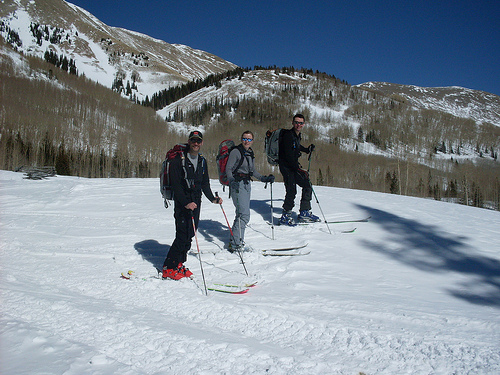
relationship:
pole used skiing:
[193, 190, 252, 301] [138, 180, 466, 365]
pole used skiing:
[244, 152, 303, 262] [35, 81, 475, 344]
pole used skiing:
[186, 200, 211, 299] [7, 100, 442, 358]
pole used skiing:
[178, 152, 316, 302] [17, 35, 477, 365]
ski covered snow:
[253, 234, 325, 266] [308, 266, 413, 306]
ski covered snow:
[244, 240, 317, 257] [300, 312, 411, 361]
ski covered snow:
[244, 240, 317, 257] [267, 320, 420, 365]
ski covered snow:
[119, 266, 259, 296] [249, 238, 305, 262]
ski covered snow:
[244, 236, 322, 264] [234, 319, 390, 358]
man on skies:
[275, 110, 321, 227] [195, 150, 361, 300]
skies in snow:
[195, 173, 378, 300] [292, 312, 421, 369]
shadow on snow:
[347, 202, 450, 264] [283, 326, 401, 364]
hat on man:
[183, 129, 205, 147] [144, 123, 236, 290]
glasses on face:
[237, 133, 253, 143] [242, 132, 253, 149]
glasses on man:
[237, 133, 253, 143] [227, 120, 261, 255]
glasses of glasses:
[237, 135, 253, 143] [240, 137, 256, 147]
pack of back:
[264, 125, 284, 164] [274, 130, 288, 166]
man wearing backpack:
[270, 106, 324, 235] [259, 128, 288, 172]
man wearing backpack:
[225, 127, 274, 255] [208, 134, 243, 191]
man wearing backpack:
[158, 129, 223, 281] [156, 142, 184, 206]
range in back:
[0, 0, 495, 219] [3, 3, 498, 213]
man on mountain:
[199, 106, 275, 278] [11, 128, 465, 373]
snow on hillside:
[0, 169, 499, 375] [29, 175, 431, 373]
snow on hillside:
[0, 169, 499, 375] [22, 158, 495, 371]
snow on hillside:
[0, 169, 499, 375] [6, 163, 449, 371]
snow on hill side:
[0, 169, 499, 375] [19, 158, 459, 373]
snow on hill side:
[36, 152, 423, 372] [39, 170, 447, 370]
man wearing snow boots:
[146, 111, 198, 294] [148, 254, 199, 297]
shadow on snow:
[347, 202, 499, 311] [37, 145, 498, 363]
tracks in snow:
[9, 177, 471, 373] [4, 164, 498, 362]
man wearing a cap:
[158, 129, 223, 281] [178, 125, 208, 149]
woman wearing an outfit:
[207, 98, 278, 265] [224, 147, 258, 251]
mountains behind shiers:
[9, 5, 498, 207] [116, 84, 336, 319]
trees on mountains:
[9, 9, 499, 239] [17, 0, 490, 223]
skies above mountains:
[64, 0, 498, 97] [9, 24, 490, 190]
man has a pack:
[275, 110, 321, 227] [263, 126, 302, 170]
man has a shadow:
[225, 127, 274, 255] [185, 199, 243, 259]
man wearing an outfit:
[225, 127, 274, 255] [207, 150, 262, 245]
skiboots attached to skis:
[143, 257, 201, 289] [91, 249, 256, 309]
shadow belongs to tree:
[347, 202, 499, 311] [327, 167, 498, 329]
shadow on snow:
[347, 202, 499, 311] [15, 137, 498, 355]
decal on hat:
[170, 125, 214, 155] [178, 117, 220, 158]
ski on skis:
[119, 266, 259, 296] [97, 249, 305, 319]